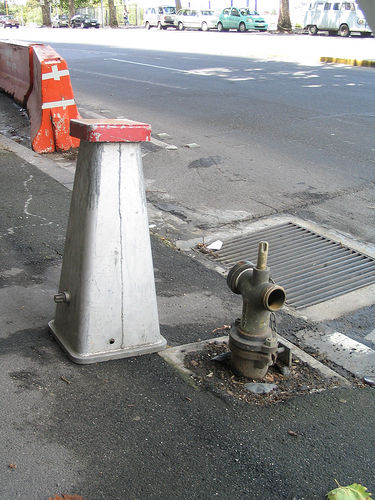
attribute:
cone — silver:
[45, 108, 168, 363]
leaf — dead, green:
[327, 475, 371, 500]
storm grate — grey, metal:
[197, 222, 374, 307]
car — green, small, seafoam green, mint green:
[214, 3, 269, 34]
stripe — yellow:
[318, 53, 375, 76]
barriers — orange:
[1, 35, 82, 153]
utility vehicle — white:
[141, 6, 175, 31]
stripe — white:
[106, 51, 203, 82]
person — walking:
[123, 5, 132, 28]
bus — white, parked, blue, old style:
[303, 0, 375, 38]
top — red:
[67, 115, 153, 147]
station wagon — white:
[172, 6, 216, 33]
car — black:
[69, 13, 100, 31]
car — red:
[2, 16, 24, 30]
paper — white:
[206, 236, 226, 254]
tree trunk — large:
[277, 0, 295, 35]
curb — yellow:
[317, 48, 374, 70]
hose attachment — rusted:
[259, 280, 288, 311]